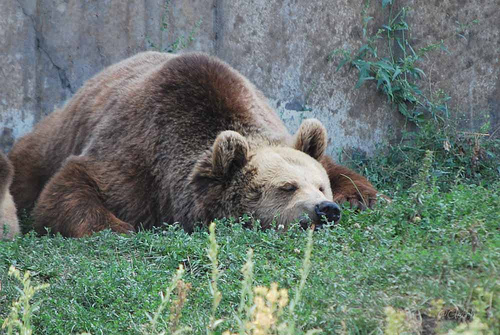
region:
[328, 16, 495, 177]
weeds growing up the wall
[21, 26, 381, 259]
bear sleeping in the grass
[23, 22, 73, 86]
crack in the stone wall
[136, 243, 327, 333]
weeds growing in the enclosure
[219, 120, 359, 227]
bear with his head on the ground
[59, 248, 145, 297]
grass growing by the bear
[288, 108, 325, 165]
rounded bear ears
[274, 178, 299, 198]
closed bear eye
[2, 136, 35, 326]
bear watching the other bear sleep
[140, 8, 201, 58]
weed growing behind the bear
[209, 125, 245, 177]
Left ear of a brown bear.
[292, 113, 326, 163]
The right ear of a brown bear.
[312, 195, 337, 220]
A black nose on a brown bear.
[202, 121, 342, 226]
The head of a brown bear.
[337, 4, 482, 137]
A green weed climbing up a stone wall.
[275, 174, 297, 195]
The right eye of a brown bear.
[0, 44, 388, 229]
A big brown bear.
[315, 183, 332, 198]
The left eye of a brown bear.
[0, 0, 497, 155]
A rock or cement wall.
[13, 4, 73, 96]
A crack in the wall.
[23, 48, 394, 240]
one large sleeping bear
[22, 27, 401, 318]
bear lying in tall grass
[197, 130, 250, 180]
one light brown bear ear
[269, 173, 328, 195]
two closed bear eyes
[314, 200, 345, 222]
one large black bear nose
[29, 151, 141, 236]
front right leg of brown bear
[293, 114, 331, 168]
left light brown bear ear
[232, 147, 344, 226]
light brown bear head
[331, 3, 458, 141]
green spiky leaves in front of rock wall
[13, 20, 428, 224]
bear in front of rock wall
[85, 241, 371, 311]
The grass is short and green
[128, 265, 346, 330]
The weeds are growing from the ground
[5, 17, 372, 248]
The bear is sleeping on the ground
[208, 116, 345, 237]
The head of the bear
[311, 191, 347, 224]
The nose of the bear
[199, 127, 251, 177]
The ear of the bear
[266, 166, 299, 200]
The eye of the bear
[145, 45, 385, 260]
The top of the bear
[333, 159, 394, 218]
The paw of the bear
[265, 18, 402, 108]
The back wall is made of cement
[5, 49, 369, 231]
big brown ear in the ground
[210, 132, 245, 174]
small furry right ear of bear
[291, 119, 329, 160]
small furry left ear of bear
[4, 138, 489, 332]
green grass in the floor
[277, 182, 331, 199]
two black eyes closed of bear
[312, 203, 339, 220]
little black nose of bear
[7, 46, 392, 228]
big brown bear sleeping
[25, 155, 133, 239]
front right leg of bear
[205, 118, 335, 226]
head of bear in the ground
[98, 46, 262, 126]
brown furry loin